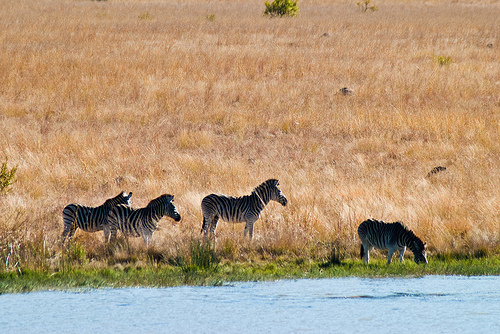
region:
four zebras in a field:
[49, 140, 491, 282]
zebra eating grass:
[353, 214, 442, 286]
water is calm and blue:
[291, 289, 433, 325]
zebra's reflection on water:
[325, 284, 479, 317]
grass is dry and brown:
[175, 67, 382, 155]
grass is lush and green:
[237, 255, 331, 277]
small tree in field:
[261, 0, 302, 20]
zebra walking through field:
[181, 170, 338, 270]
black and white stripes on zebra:
[181, 170, 290, 257]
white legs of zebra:
[355, 241, 409, 268]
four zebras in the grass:
[53, 175, 444, 277]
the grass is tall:
[71, 85, 217, 172]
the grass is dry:
[128, 110, 347, 220]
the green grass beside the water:
[31, 262, 498, 294]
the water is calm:
[320, 299, 410, 329]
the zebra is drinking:
[347, 214, 462, 282]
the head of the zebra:
[142, 187, 189, 227]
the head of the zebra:
[255, 171, 296, 215]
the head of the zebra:
[403, 236, 436, 266]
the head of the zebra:
[113, 186, 141, 201]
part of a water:
[340, 294, 370, 331]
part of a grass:
[306, 239, 343, 281]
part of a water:
[331, 305, 353, 331]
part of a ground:
[273, 231, 299, 277]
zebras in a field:
[50, 170, 441, 277]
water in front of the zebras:
[3, 264, 497, 331]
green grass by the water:
[0, 252, 498, 289]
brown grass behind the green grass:
[2, 2, 498, 264]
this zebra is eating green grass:
[353, 212, 428, 271]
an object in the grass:
[420, 159, 447, 185]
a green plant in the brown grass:
[257, 0, 303, 24]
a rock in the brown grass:
[337, 82, 359, 103]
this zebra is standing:
[195, 166, 290, 247]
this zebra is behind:
[55, 187, 135, 242]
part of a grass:
[278, 127, 320, 179]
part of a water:
[326, 271, 361, 316]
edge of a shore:
[263, 260, 308, 296]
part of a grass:
[261, 245, 304, 298]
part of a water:
[236, 263, 278, 321]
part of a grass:
[299, 238, 317, 261]